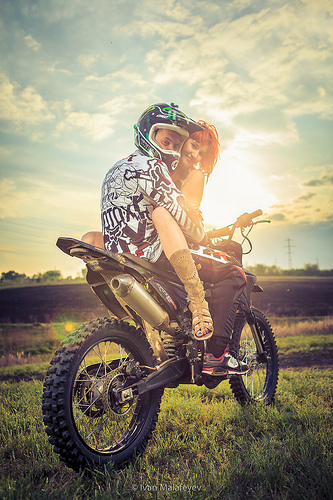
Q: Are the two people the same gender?
A: No, they are both male and female.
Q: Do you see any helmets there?
A: Yes, there is a helmet.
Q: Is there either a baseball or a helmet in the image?
A: Yes, there is a helmet.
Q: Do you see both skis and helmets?
A: No, there is a helmet but no skis.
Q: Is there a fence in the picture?
A: No, there are no fences.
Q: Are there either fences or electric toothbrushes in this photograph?
A: No, there are no fences or electric toothbrushes.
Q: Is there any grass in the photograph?
A: Yes, there is grass.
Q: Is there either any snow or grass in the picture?
A: Yes, there is grass.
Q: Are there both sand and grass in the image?
A: No, there is grass but no sand.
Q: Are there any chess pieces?
A: No, there are no chess pieces.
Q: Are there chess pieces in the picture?
A: No, there are no chess pieces.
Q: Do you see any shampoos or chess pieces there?
A: No, there are no chess pieces or shampoos.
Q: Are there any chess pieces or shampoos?
A: No, there are no chess pieces or shampoos.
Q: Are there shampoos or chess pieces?
A: No, there are no chess pieces or shampoos.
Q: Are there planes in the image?
A: No, there are no planes.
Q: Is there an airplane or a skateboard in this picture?
A: No, there are no airplanes or skateboards.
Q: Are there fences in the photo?
A: No, there are no fences.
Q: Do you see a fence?
A: No, there are no fences.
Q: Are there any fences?
A: No, there are no fences.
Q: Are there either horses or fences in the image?
A: No, there are no fences or horses.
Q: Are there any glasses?
A: No, there are no glasses.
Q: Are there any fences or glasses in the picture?
A: No, there are no glasses or fences.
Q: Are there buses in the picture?
A: No, there are no buses.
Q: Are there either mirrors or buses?
A: No, there are no buses or mirrors.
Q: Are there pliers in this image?
A: No, there are no pliers.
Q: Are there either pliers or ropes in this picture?
A: No, there are no pliers or ropes.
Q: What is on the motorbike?
A: The chain is on the motorbike.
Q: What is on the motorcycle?
A: The chain is on the motorbike.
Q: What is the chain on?
A: The chain is on the motorcycle.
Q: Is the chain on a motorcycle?
A: Yes, the chain is on a motorcycle.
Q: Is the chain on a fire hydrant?
A: No, the chain is on a motorcycle.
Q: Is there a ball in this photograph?
A: No, there are no balls.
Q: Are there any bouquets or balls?
A: No, there are no balls or bouquets.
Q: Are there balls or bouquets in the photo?
A: No, there are no balls or bouquets.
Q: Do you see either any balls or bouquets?
A: No, there are no balls or bouquets.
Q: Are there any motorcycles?
A: Yes, there is a motorcycle.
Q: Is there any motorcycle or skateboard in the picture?
A: Yes, there is a motorcycle.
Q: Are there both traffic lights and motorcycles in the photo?
A: No, there is a motorcycle but no traffic lights.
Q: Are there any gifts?
A: No, there are no gifts.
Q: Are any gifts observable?
A: No, there are no gifts.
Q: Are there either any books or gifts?
A: No, there are no gifts or books.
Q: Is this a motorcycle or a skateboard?
A: This is a motorcycle.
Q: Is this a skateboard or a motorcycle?
A: This is a motorcycle.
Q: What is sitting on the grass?
A: The motorcycle is sitting on the grass.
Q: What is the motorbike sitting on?
A: The motorbike is sitting on the grass.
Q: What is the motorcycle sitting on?
A: The motorbike is sitting on the grass.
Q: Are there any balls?
A: No, there are no balls.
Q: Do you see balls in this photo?
A: No, there are no balls.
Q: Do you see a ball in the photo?
A: No, there are no balls.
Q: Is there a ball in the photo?
A: No, there are no balls.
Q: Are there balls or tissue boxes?
A: No, there are no balls or tissue boxes.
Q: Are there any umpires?
A: No, there are no umpires.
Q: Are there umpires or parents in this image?
A: No, there are no umpires or parents.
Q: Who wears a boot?
A: The girl wears a boot.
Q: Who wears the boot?
A: The girl wears a boot.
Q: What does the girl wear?
A: The girl wears a boot.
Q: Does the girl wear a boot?
A: Yes, the girl wears a boot.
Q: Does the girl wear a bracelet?
A: No, the girl wears a boot.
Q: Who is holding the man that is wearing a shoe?
A: The girl is holding the man.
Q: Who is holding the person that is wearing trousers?
A: The girl is holding the man.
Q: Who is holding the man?
A: The girl is holding the man.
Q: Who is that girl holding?
A: The girl is holding the man.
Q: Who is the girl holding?
A: The girl is holding the man.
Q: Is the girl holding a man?
A: Yes, the girl is holding a man.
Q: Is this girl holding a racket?
A: No, the girl is holding a man.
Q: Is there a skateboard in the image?
A: No, there are no skateboards.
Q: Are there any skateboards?
A: No, there are no skateboards.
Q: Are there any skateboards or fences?
A: No, there are no skateboards or fences.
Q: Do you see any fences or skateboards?
A: No, there are no skateboards or fences.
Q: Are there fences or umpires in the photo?
A: No, there are no umpires or fences.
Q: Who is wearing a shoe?
A: The man is wearing a shoe.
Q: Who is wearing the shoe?
A: The man is wearing a shoe.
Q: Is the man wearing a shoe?
A: Yes, the man is wearing a shoe.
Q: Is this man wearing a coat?
A: No, the man is wearing a shoe.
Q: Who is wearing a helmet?
A: The man is wearing a helmet.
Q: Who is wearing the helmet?
A: The man is wearing a helmet.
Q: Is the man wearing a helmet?
A: Yes, the man is wearing a helmet.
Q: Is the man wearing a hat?
A: No, the man is wearing a helmet.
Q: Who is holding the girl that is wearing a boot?
A: The man is holding the girl.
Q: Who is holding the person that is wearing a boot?
A: The man is holding the girl.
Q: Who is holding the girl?
A: The man is holding the girl.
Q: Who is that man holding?
A: The man is holding the girl.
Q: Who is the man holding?
A: The man is holding the girl.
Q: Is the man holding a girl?
A: Yes, the man is holding a girl.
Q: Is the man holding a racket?
A: No, the man is holding a girl.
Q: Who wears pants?
A: The man wears pants.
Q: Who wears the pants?
A: The man wears pants.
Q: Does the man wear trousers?
A: Yes, the man wears trousers.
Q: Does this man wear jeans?
A: No, the man wears trousers.